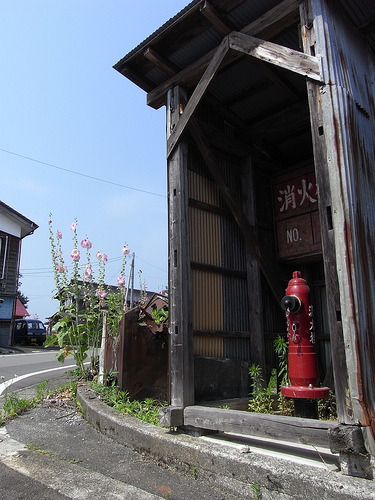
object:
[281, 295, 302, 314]
black knob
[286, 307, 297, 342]
chain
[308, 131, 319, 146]
ground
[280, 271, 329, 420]
fire hydrant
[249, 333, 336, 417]
weeds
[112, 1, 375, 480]
building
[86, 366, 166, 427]
grass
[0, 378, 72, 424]
grass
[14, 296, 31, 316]
van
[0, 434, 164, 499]
line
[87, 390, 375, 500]
sidewalk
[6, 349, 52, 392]
street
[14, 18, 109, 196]
sky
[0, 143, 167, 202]
power line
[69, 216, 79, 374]
stalk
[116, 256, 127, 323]
stalk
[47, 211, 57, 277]
stalk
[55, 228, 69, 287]
stalk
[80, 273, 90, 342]
stalk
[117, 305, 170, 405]
fence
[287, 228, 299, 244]
letters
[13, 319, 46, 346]
car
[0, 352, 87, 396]
line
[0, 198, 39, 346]
building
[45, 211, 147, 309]
flowers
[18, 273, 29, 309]
tree